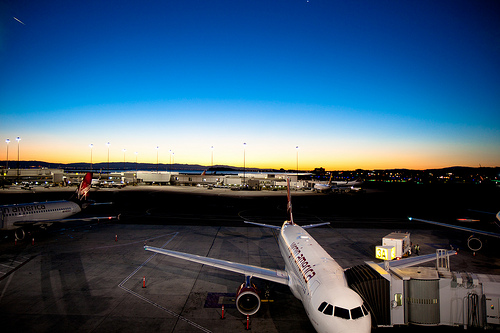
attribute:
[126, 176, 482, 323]
plane — white, landed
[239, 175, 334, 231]
tail — red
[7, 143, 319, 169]
lights — on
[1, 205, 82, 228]
windows — black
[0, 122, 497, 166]
blue — white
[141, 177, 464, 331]
jet — white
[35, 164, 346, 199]
terminal — adjacent